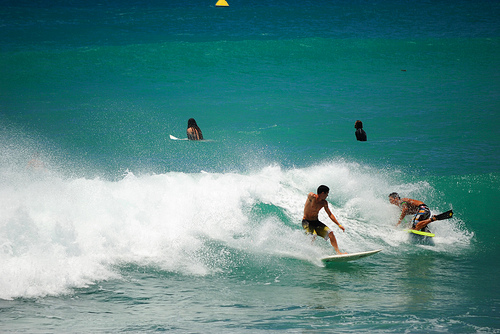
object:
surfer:
[301, 184, 348, 256]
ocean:
[59, 58, 139, 122]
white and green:
[76, 129, 156, 177]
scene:
[140, 54, 426, 215]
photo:
[0, 35, 500, 317]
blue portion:
[223, 12, 308, 47]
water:
[192, 61, 329, 110]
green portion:
[44, 81, 124, 126]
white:
[107, 202, 169, 234]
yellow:
[211, 0, 229, 8]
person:
[185, 118, 204, 143]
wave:
[43, 193, 179, 279]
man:
[300, 185, 345, 256]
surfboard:
[321, 248, 383, 262]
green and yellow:
[405, 228, 436, 243]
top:
[351, 249, 382, 260]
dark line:
[300, 11, 353, 23]